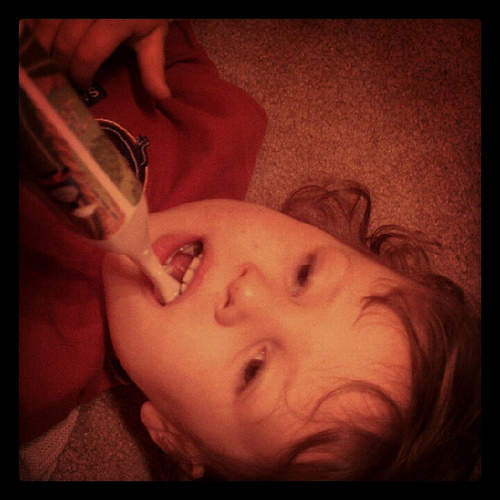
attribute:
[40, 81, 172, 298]
toothbrush — white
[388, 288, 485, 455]
hair — brown, long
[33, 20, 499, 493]
boy — white, brushing, small, looking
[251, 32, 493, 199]
carpet — light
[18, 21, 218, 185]
shirt — red, long